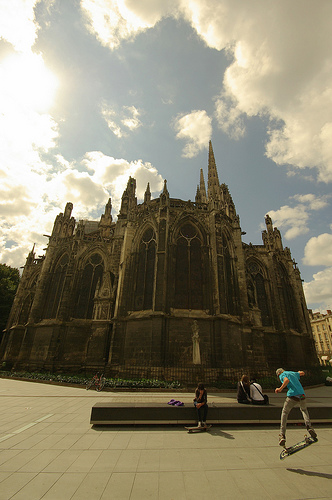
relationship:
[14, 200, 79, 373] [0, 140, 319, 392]
tower on cathedral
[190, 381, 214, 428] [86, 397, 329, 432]
skateboarder sitting on bench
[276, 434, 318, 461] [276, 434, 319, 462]
skateboard on trick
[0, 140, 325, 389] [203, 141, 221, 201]
cathedral with spires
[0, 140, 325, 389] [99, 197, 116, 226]
cathedral with steeples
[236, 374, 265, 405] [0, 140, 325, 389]
couple sitting outside cathedral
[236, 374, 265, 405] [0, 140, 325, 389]
couple relaxing outside cathedral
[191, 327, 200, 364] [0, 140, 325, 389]
statue in front cathedral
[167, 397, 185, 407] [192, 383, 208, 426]
purple clothing beside person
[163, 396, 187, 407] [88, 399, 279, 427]
purple clothing on bench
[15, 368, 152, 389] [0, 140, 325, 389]
greenery in front of cathedral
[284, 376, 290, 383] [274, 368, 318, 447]
elbow of a boy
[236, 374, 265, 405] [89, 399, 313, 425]
couple on a bench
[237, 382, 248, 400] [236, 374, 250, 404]
back of a girl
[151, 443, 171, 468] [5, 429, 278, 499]
section of a skating park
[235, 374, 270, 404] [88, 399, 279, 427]
couple on a bench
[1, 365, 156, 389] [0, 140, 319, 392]
path in front of a cathedral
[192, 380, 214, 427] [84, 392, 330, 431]
girl sitting on bench